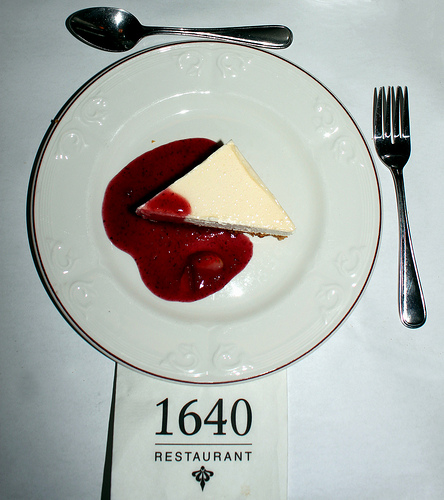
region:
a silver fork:
[311, 54, 430, 219]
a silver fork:
[324, 41, 441, 327]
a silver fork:
[336, 58, 427, 300]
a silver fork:
[354, 68, 442, 275]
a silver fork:
[320, 77, 429, 285]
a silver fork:
[341, 62, 416, 389]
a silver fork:
[328, 90, 416, 329]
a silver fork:
[326, 83, 416, 333]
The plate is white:
[110, 321, 269, 364]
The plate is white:
[240, 337, 295, 415]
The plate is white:
[221, 292, 281, 359]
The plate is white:
[243, 286, 331, 447]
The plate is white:
[194, 301, 335, 393]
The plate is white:
[178, 310, 290, 405]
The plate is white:
[247, 290, 312, 362]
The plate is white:
[183, 306, 284, 397]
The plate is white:
[190, 279, 281, 379]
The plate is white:
[183, 285, 285, 410]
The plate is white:
[105, 294, 380, 399]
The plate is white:
[214, 292, 234, 330]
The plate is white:
[292, 262, 333, 347]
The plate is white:
[245, 333, 270, 426]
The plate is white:
[215, 354, 239, 405]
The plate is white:
[204, 333, 233, 374]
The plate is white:
[212, 332, 303, 484]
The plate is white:
[240, 343, 298, 439]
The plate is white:
[212, 297, 262, 388]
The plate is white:
[201, 272, 278, 414]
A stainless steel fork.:
[357, 74, 442, 218]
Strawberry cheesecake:
[127, 135, 310, 245]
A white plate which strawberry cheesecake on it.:
[117, 76, 326, 130]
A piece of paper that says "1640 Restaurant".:
[123, 392, 282, 494]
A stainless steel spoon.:
[49, 0, 338, 57]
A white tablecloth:
[324, 387, 424, 484]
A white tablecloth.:
[21, 367, 90, 484]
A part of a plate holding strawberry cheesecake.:
[148, 306, 255, 360]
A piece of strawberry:
[177, 248, 242, 290]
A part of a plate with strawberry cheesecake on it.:
[295, 107, 355, 204]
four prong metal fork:
[366, 76, 437, 337]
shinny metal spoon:
[55, 3, 301, 55]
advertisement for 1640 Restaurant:
[111, 385, 287, 497]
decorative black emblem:
[188, 463, 217, 494]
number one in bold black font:
[149, 387, 176, 442]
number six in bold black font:
[174, 390, 203, 440]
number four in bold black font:
[202, 393, 229, 439]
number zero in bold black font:
[228, 395, 256, 440]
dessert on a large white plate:
[23, 41, 383, 386]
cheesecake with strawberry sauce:
[81, 114, 313, 306]